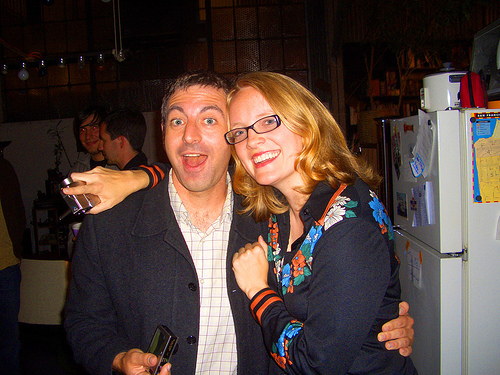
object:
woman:
[226, 73, 411, 370]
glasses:
[222, 115, 284, 147]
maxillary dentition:
[246, 148, 284, 163]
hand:
[230, 232, 270, 300]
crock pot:
[419, 68, 472, 111]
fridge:
[382, 105, 498, 374]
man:
[58, 74, 292, 375]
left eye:
[198, 116, 218, 125]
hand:
[60, 159, 151, 216]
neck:
[267, 167, 329, 224]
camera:
[145, 326, 178, 375]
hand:
[108, 345, 177, 374]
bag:
[455, 70, 483, 107]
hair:
[157, 66, 236, 110]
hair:
[225, 67, 381, 222]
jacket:
[65, 187, 286, 375]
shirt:
[163, 166, 236, 374]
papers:
[409, 112, 435, 176]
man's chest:
[217, 207, 279, 330]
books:
[401, 44, 419, 72]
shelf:
[346, 97, 420, 149]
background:
[0, 2, 499, 375]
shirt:
[246, 188, 417, 374]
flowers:
[287, 247, 312, 269]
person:
[70, 110, 114, 175]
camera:
[56, 168, 105, 215]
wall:
[1, 6, 325, 258]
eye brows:
[161, 117, 192, 128]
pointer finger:
[60, 181, 107, 199]